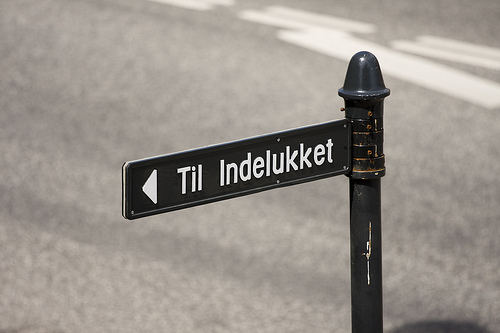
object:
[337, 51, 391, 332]
pole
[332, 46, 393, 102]
tip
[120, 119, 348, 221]
til indelukket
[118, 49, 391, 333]
sign post